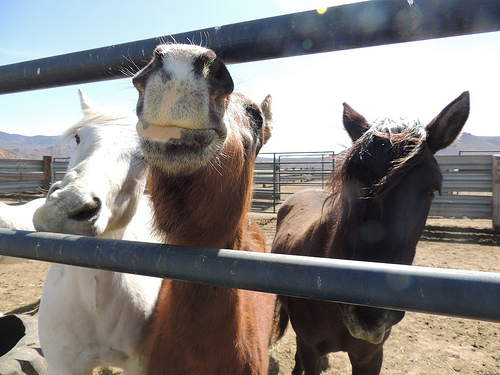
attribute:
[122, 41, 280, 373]
horse — brown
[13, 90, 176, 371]
horse — white